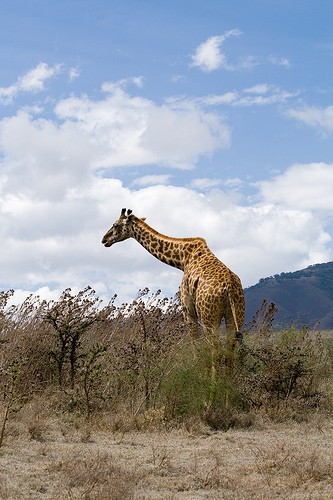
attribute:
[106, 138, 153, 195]
clouds — white 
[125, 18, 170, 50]
sky — blue 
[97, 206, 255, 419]
giraffe — an adult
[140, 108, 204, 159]
clouds — white 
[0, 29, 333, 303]
clouds — white 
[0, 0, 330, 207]
sky — blue 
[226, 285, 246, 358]
tail — black 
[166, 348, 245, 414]
brush — green 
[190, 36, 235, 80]
clouds — white 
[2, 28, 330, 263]
sky — blue 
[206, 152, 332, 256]
clouds — white 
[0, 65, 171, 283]
clouds — white 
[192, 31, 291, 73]
cloud — white 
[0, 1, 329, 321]
sky — blue 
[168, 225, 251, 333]
giraffe — Tall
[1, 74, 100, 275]
clouds — white 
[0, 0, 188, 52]
sky — blue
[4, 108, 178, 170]
clouds — white 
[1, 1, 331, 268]
sky — blue 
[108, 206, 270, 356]
giraffe — sleepy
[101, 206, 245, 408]
giraffe — spotted, brown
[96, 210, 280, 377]
giraffe — horned